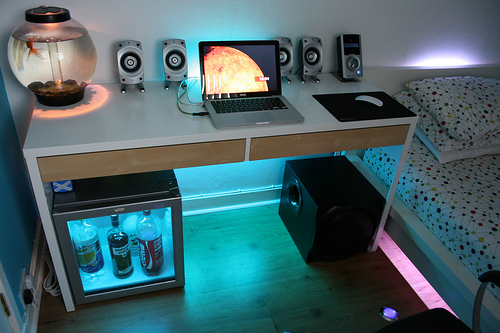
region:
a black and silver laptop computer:
[197, 37, 306, 132]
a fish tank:
[5, 4, 99, 106]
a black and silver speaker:
[297, 35, 324, 85]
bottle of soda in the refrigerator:
[135, 209, 165, 275]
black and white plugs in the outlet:
[16, 265, 37, 310]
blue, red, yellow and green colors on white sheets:
[435, 168, 498, 232]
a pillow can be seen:
[393, 73, 498, 163]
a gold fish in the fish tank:
[6, 4, 98, 109]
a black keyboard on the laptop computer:
[210, 95, 288, 117]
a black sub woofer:
[276, 153, 384, 263]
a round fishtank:
[9, 6, 105, 115]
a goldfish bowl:
[4, 7, 107, 118]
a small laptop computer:
[192, 31, 307, 137]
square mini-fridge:
[58, 180, 201, 313]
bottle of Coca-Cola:
[135, 208, 168, 275]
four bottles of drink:
[70, 216, 168, 273]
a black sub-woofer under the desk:
[277, 156, 385, 268]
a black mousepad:
[310, 85, 422, 129]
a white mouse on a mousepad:
[347, 92, 389, 112]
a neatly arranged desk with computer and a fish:
[7, 3, 422, 305]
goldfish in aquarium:
[4, 7, 72, 64]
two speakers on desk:
[109, 31, 191, 92]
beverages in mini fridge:
[47, 192, 197, 311]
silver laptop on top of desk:
[187, 31, 337, 150]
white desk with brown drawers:
[16, 68, 428, 303]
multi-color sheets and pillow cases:
[376, 34, 498, 293]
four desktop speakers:
[108, 27, 333, 92]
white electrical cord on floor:
[19, 212, 66, 317]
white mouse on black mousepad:
[310, 82, 421, 137]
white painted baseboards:
[177, 170, 284, 219]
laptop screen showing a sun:
[191, 30, 310, 148]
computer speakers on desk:
[111, 34, 191, 101]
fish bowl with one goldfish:
[5, 5, 120, 124]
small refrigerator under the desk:
[49, 193, 200, 304]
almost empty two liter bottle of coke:
[133, 201, 184, 302]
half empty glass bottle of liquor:
[100, 211, 140, 291]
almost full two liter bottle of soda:
[67, 216, 104, 287]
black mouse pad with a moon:
[306, 84, 411, 144]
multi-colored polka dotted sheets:
[400, 64, 487, 251]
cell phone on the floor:
[370, 296, 408, 326]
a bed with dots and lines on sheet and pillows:
[352, 67, 499, 330]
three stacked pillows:
[390, 61, 496, 180]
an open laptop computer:
[176, 31, 306, 141]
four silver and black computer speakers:
[112, 26, 329, 86]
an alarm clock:
[327, 17, 370, 87]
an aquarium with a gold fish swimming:
[5, 3, 104, 108]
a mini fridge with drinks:
[49, 173, 196, 307]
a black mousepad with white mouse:
[305, 82, 418, 136]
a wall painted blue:
[0, 72, 43, 327]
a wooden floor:
[32, 194, 461, 331]